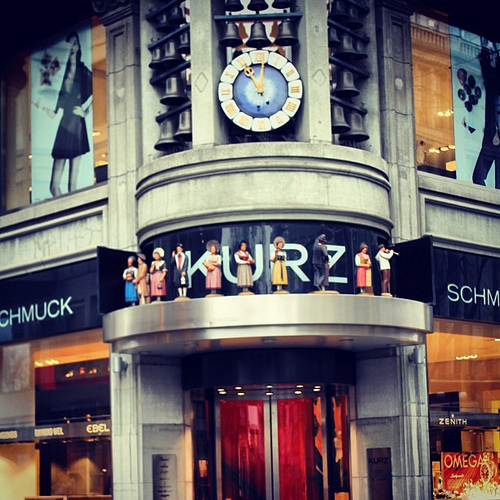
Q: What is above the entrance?
A: A sign with many people on it.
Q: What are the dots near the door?
A: Recessed lighting.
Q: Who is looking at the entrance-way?
A: The photographer.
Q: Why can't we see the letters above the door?
A: There are pictures of people obstructing them.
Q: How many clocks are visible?
A: One.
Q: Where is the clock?
A: Above the entrance-way.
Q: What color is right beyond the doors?
A: Red.